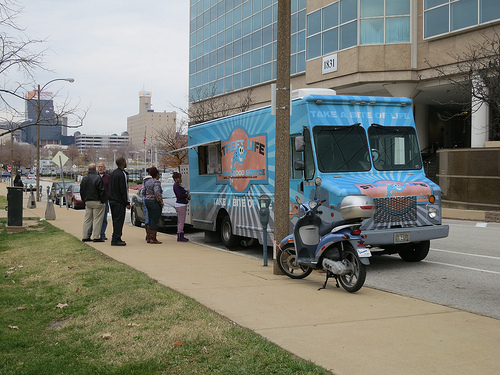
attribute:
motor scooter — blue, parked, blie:
[277, 195, 373, 296]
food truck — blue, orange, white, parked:
[165, 86, 450, 264]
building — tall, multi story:
[186, 3, 499, 227]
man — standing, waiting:
[107, 156, 133, 250]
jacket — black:
[103, 168, 133, 206]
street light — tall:
[271, 1, 296, 278]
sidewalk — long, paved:
[2, 182, 495, 373]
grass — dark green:
[2, 197, 329, 374]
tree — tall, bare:
[2, 1, 93, 240]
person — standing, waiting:
[171, 168, 194, 242]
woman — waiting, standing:
[145, 164, 167, 248]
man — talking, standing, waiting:
[81, 163, 109, 245]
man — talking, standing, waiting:
[95, 160, 111, 240]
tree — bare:
[421, 29, 499, 147]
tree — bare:
[152, 117, 188, 178]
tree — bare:
[171, 76, 256, 127]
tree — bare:
[2, 138, 36, 171]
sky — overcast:
[0, 1, 192, 140]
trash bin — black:
[7, 183, 28, 229]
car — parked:
[130, 185, 202, 235]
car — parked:
[63, 181, 87, 210]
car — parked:
[49, 176, 78, 206]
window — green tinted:
[358, 14, 386, 48]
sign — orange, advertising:
[214, 125, 270, 199]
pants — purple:
[173, 203, 188, 234]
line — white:
[428, 245, 499, 261]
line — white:
[380, 253, 499, 279]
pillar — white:
[471, 74, 490, 151]